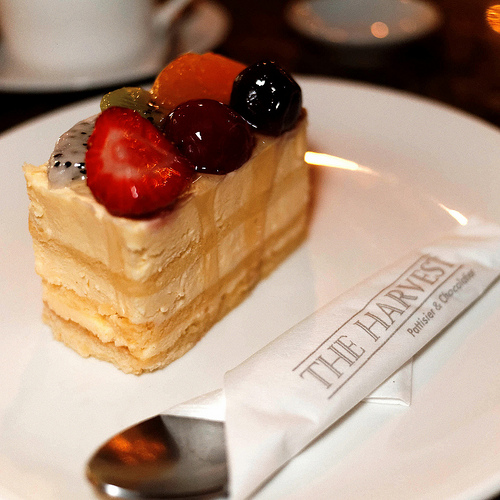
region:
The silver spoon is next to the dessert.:
[81, 210, 498, 498]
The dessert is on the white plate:
[4, 70, 498, 490]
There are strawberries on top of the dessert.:
[89, 99, 192, 218]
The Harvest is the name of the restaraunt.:
[292, 249, 486, 406]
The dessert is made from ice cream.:
[20, 110, 311, 375]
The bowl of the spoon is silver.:
[82, 409, 233, 494]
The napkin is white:
[163, 211, 498, 498]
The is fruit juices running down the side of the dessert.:
[191, 164, 231, 330]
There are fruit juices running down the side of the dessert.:
[244, 136, 294, 286]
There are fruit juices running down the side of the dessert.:
[99, 206, 129, 322]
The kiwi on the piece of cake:
[59, 96, 160, 180]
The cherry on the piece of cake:
[182, 109, 247, 174]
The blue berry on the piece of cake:
[236, 53, 300, 137]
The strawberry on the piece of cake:
[77, 106, 198, 210]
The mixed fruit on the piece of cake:
[52, 55, 326, 185]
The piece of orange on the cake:
[136, 56, 260, 96]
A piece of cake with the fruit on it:
[16, 46, 337, 371]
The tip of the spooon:
[83, 418, 218, 490]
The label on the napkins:
[293, 233, 458, 427]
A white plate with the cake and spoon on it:
[0, 46, 488, 496]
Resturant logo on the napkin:
[275, 243, 487, 409]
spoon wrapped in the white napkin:
[76, 397, 258, 498]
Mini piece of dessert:
[12, 43, 341, 388]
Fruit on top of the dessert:
[46, 49, 307, 222]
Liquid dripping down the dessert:
[176, 123, 297, 305]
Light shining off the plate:
[306, 131, 472, 254]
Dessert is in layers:
[20, 112, 348, 382]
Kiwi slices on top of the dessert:
[38, 84, 166, 206]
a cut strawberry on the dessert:
[79, 103, 201, 240]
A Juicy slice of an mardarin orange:
[150, 46, 250, 114]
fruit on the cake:
[11, 43, 321, 378]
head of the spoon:
[73, 409, 235, 496]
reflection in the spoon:
[118, 434, 184, 476]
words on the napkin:
[279, 236, 496, 402]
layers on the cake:
[65, 215, 119, 346]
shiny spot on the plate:
[323, 149, 361, 174]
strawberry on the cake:
[90, 108, 184, 224]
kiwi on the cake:
[107, 87, 157, 112]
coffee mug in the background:
[4, 8, 161, 73]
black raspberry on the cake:
[227, 52, 301, 136]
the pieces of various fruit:
[47, 52, 303, 218]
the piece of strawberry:
[85, 105, 187, 215]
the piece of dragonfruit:
[47, 113, 99, 188]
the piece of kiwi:
[98, 87, 165, 123]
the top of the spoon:
[85, 414, 227, 499]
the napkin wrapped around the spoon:
[159, 216, 499, 499]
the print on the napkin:
[292, 254, 474, 399]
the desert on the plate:
[22, 51, 308, 376]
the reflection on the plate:
[304, 148, 379, 177]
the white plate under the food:
[0, 77, 499, 497]